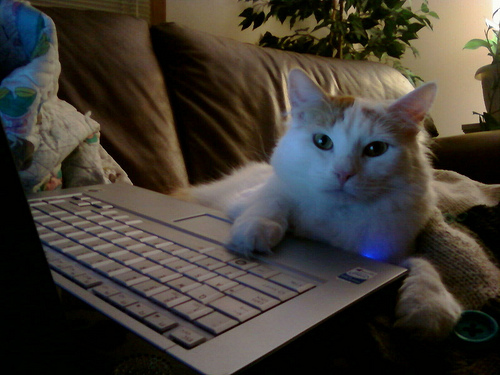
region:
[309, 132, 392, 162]
Cat's eyes looking forward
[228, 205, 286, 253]
White cat paw on a laptop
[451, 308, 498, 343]
Green button on a sweater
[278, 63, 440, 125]
Two cat ears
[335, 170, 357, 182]
Pink nose on a cat's face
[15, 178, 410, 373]
Keyboard on a laptop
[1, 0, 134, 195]
Blanket on a couch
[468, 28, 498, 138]
Plant on a table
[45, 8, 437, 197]
Cushions on a brown couch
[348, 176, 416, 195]
Whiskers on a cat's face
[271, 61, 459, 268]
cat looking at camera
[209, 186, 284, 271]
cat paw on laptop computer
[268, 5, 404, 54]
green leaves on fake tree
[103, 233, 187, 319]
silver keys on the computer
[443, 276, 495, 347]
green soda lid by cat's paw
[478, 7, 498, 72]
green plant on back table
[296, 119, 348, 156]
left eye on cat in photo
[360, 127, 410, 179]
right eye on cat in photo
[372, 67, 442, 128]
right ear on car in photo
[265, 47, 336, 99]
left ear on cat in photo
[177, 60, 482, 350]
Cat on the couch.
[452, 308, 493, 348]
Green button on the sweater.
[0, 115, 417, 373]
laptop on the couch.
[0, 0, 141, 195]
blanket on the couch.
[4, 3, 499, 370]
brown couch in the forefront.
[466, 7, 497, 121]
Plant on the table.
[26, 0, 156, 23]
blinds on the window.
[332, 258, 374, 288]
Sticker on the computer.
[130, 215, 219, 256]
spacebar on the keyboard.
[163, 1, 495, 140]
white wall in the background.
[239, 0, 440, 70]
a green plant behind a couch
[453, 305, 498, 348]
a green button on a sweater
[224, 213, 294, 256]
the paw of a cat on a laptop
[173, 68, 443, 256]
a white and orange cat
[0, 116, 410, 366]
a silver laptop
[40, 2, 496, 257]
a brown couch under a cat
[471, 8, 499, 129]
a plant on a table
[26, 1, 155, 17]
blinds in a window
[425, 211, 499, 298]
a grey sweater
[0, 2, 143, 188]
a child's blanket on a couch